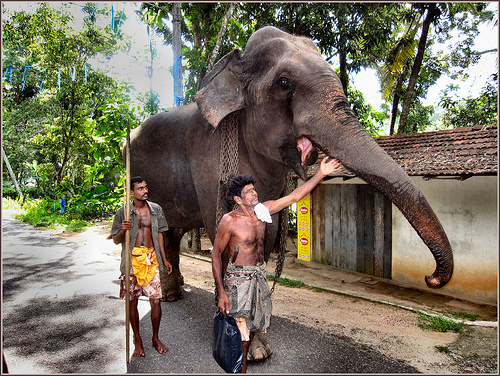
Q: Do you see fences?
A: No, there are no fences.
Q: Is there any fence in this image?
A: No, there are no fences.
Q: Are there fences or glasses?
A: No, there are no fences or glasses.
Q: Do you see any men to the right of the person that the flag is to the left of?
A: Yes, there is a man to the right of the person.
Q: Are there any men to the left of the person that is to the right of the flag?
A: No, the man is to the right of the person.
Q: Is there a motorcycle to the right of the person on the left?
A: No, there is a man to the right of the person.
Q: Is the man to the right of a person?
A: Yes, the man is to the right of a person.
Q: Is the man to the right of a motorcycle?
A: No, the man is to the right of a person.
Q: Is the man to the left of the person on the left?
A: No, the man is to the right of the person.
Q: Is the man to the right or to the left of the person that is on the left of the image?
A: The man is to the right of the person.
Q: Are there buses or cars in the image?
A: No, there are no cars or buses.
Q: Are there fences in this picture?
A: No, there are no fences.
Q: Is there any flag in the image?
A: Yes, there is a flag.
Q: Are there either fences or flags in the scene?
A: Yes, there is a flag.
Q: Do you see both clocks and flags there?
A: No, there is a flag but no clocks.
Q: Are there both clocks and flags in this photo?
A: No, there is a flag but no clocks.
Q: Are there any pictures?
A: No, there are no pictures.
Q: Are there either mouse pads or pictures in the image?
A: No, there are no pictures or mouse pads.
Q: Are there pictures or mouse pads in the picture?
A: No, there are no pictures or mouse pads.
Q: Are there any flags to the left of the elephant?
A: Yes, there is a flag to the left of the elephant.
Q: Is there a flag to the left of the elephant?
A: Yes, there is a flag to the left of the elephant.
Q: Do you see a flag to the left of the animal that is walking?
A: Yes, there is a flag to the left of the elephant.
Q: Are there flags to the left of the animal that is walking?
A: Yes, there is a flag to the left of the elephant.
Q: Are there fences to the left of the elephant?
A: No, there is a flag to the left of the elephant.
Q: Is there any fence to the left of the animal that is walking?
A: No, there is a flag to the left of the elephant.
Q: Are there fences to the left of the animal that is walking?
A: No, there is a flag to the left of the elephant.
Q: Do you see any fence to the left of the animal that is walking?
A: No, there is a flag to the left of the elephant.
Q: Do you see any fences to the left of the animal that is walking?
A: No, there is a flag to the left of the elephant.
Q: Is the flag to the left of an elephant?
A: Yes, the flag is to the left of an elephant.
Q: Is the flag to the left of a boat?
A: No, the flag is to the left of an elephant.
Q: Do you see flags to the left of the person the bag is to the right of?
A: Yes, there is a flag to the left of the person.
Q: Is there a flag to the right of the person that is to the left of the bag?
A: No, the flag is to the left of the person.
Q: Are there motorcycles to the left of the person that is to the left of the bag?
A: No, there is a flag to the left of the person.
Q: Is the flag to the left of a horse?
A: No, the flag is to the left of a person.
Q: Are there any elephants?
A: Yes, there is an elephant.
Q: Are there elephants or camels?
A: Yes, there is an elephant.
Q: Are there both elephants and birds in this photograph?
A: No, there is an elephant but no birds.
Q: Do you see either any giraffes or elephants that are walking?
A: Yes, the elephant is walking.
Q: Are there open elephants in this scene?
A: Yes, there is an open elephant.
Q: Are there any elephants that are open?
A: Yes, there is an open elephant.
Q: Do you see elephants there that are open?
A: Yes, there is an elephant that is open.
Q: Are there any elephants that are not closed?
A: Yes, there is a open elephant.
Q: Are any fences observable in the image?
A: No, there are no fences.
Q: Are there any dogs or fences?
A: No, there are no fences or dogs.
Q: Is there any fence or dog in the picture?
A: No, there are no fences or dogs.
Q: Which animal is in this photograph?
A: The animal is an elephant.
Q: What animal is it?
A: The animal is an elephant.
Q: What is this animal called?
A: That is an elephant.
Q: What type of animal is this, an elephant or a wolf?
A: That is an elephant.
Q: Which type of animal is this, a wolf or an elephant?
A: That is an elephant.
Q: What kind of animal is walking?
A: The animal is an elephant.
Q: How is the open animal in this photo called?
A: The animal is an elephant.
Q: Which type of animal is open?
A: The animal is an elephant.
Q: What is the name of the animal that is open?
A: The animal is an elephant.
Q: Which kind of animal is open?
A: The animal is an elephant.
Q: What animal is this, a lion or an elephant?
A: This is an elephant.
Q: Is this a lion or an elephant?
A: This is an elephant.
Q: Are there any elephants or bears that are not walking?
A: No, there is an elephant but it is walking.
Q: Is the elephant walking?
A: Yes, the elephant is walking.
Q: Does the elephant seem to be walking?
A: Yes, the elephant is walking.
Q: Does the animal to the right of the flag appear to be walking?
A: Yes, the elephant is walking.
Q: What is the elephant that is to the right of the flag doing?
A: The elephant is walking.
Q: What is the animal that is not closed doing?
A: The elephant is walking.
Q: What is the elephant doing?
A: The elephant is walking.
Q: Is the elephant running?
A: No, the elephant is walking.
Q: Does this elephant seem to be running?
A: No, the elephant is walking.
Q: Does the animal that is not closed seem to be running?
A: No, the elephant is walking.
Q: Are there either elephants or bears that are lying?
A: No, there is an elephant but it is walking.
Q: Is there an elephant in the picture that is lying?
A: No, there is an elephant but it is walking.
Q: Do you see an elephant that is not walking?
A: No, there is an elephant but it is walking.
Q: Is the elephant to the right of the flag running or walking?
A: The elephant is walking.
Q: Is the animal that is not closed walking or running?
A: The elephant is walking.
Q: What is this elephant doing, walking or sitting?
A: The elephant is walking.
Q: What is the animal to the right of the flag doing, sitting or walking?
A: The elephant is walking.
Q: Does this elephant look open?
A: Yes, the elephant is open.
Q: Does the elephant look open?
A: Yes, the elephant is open.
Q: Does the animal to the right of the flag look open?
A: Yes, the elephant is open.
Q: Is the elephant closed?
A: No, the elephant is open.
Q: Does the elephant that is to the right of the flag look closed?
A: No, the elephant is open.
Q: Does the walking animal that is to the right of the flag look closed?
A: No, the elephant is open.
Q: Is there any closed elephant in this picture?
A: No, there is an elephant but it is open.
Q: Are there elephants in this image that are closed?
A: No, there is an elephant but it is open.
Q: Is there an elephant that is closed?
A: No, there is an elephant but it is open.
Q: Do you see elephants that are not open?
A: No, there is an elephant but it is open.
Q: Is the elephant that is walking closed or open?
A: The elephant is open.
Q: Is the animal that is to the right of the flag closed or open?
A: The elephant is open.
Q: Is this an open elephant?
A: Yes, this is an open elephant.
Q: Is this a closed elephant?
A: No, this is an open elephant.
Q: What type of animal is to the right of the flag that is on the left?
A: The animal is an elephant.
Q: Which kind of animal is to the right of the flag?
A: The animal is an elephant.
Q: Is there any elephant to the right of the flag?
A: Yes, there is an elephant to the right of the flag.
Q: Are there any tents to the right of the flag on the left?
A: No, there is an elephant to the right of the flag.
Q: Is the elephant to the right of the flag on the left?
A: Yes, the elephant is to the right of the flag.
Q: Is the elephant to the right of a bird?
A: No, the elephant is to the right of the flag.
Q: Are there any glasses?
A: No, there are no glasses.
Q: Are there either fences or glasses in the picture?
A: No, there are no glasses or fences.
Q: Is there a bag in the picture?
A: Yes, there is a bag.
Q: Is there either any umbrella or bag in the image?
A: Yes, there is a bag.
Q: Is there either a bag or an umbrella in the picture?
A: Yes, there is a bag.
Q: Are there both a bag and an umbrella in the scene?
A: No, there is a bag but no umbrellas.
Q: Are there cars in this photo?
A: No, there are no cars.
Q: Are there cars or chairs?
A: No, there are no cars or chairs.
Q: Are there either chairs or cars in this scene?
A: No, there are no cars or chairs.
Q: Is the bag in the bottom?
A: Yes, the bag is in the bottom of the image.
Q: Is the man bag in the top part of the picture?
A: No, the bag is in the bottom of the image.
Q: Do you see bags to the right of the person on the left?
A: Yes, there is a bag to the right of the person.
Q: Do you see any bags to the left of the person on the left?
A: No, the bag is to the right of the person.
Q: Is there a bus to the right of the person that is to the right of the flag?
A: No, there is a bag to the right of the person.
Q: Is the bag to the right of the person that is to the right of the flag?
A: Yes, the bag is to the right of the person.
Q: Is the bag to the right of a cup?
A: No, the bag is to the right of the person.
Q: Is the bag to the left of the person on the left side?
A: No, the bag is to the right of the person.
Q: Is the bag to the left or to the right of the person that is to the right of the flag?
A: The bag is to the right of the person.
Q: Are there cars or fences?
A: No, there are no cars or fences.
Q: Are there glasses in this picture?
A: No, there are no glasses.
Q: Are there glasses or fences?
A: No, there are no glasses or fences.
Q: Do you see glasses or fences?
A: No, there are no glasses or fences.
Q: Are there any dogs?
A: No, there are no dogs.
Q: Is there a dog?
A: No, there are no dogs.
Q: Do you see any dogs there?
A: No, there are no dogs.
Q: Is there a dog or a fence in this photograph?
A: No, there are no dogs or fences.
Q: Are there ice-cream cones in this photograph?
A: No, there are no ice-cream cones.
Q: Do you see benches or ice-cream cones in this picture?
A: No, there are no ice-cream cones or benches.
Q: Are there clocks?
A: No, there are no clocks.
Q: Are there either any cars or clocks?
A: No, there are no clocks or cars.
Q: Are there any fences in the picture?
A: No, there are no fences.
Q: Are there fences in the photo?
A: No, there are no fences.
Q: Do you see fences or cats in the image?
A: No, there are no fences or cats.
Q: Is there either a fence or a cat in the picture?
A: No, there are no fences or cats.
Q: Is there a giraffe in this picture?
A: No, there are no giraffes.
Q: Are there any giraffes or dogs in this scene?
A: No, there are no giraffes or dogs.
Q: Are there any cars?
A: No, there are no cars.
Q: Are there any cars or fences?
A: No, there are no cars or fences.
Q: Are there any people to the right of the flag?
A: Yes, there is a person to the right of the flag.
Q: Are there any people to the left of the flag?
A: No, the person is to the right of the flag.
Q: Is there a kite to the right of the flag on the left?
A: No, there is a person to the right of the flag.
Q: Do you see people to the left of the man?
A: Yes, there is a person to the left of the man.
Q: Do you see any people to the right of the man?
A: No, the person is to the left of the man.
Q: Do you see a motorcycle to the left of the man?
A: No, there is a person to the left of the man.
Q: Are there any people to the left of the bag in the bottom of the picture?
A: Yes, there is a person to the left of the bag.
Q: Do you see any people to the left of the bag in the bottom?
A: Yes, there is a person to the left of the bag.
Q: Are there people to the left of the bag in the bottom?
A: Yes, there is a person to the left of the bag.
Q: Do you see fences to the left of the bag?
A: No, there is a person to the left of the bag.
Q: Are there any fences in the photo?
A: No, there are no fences.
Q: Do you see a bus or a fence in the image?
A: No, there are no fences or buses.